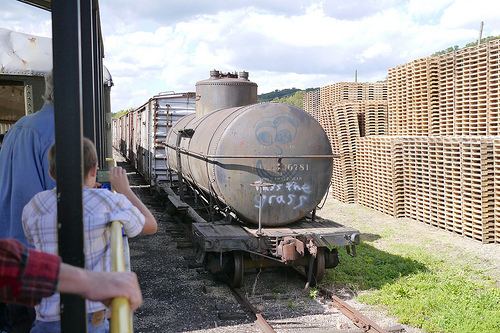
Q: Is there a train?
A: Yes, there is a train.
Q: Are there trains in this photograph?
A: Yes, there is a train.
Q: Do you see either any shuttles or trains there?
A: Yes, there is a train.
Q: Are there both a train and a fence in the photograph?
A: No, there is a train but no fences.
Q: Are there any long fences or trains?
A: Yes, there is a long train.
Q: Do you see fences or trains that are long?
A: Yes, the train is long.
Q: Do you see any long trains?
A: Yes, there is a long train.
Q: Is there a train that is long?
A: Yes, there is a train that is long.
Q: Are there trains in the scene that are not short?
A: Yes, there is a long train.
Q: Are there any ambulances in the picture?
A: No, there are no ambulances.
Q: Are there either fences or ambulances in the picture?
A: No, there are no ambulances or fences.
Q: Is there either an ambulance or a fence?
A: No, there are no ambulances or fences.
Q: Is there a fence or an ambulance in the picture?
A: No, there are no ambulances or fences.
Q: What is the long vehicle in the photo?
A: The vehicle is a train.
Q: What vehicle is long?
A: The vehicle is a train.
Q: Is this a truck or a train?
A: This is a train.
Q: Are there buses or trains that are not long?
A: No, there is a train but it is long.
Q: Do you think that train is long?
A: Yes, the train is long.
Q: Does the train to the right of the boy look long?
A: Yes, the train is long.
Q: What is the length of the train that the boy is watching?
A: The train is long.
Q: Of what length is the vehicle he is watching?
A: The train is long.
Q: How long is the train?
A: The train is long.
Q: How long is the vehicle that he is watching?
A: The train is long.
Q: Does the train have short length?
A: No, the train is long.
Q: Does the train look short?
A: No, the train is long.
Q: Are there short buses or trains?
A: No, there is a train but it is long.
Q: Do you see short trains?
A: No, there is a train but it is long.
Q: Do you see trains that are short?
A: No, there is a train but it is long.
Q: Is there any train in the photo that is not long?
A: No, there is a train but it is long.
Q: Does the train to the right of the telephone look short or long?
A: The train is long.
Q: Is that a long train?
A: Yes, that is a long train.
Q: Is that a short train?
A: No, that is a long train.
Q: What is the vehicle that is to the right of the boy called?
A: The vehicle is a train.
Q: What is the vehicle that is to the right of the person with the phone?
A: The vehicle is a train.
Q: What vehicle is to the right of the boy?
A: The vehicle is a train.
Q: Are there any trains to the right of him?
A: Yes, there is a train to the right of the boy.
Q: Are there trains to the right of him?
A: Yes, there is a train to the right of the boy.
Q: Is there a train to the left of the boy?
A: No, the train is to the right of the boy.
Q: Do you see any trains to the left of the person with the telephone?
A: No, the train is to the right of the boy.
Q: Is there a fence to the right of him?
A: No, there is a train to the right of the boy.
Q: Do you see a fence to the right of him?
A: No, there is a train to the right of the boy.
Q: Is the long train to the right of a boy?
A: Yes, the train is to the right of a boy.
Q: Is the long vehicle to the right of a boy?
A: Yes, the train is to the right of a boy.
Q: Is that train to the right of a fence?
A: No, the train is to the right of a boy.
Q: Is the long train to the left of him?
A: No, the train is to the right of the boy.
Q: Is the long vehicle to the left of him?
A: No, the train is to the right of the boy.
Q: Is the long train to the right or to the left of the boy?
A: The train is to the right of the boy.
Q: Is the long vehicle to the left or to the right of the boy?
A: The train is to the right of the boy.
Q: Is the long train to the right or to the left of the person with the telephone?
A: The train is to the right of the boy.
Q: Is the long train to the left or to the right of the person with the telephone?
A: The train is to the right of the boy.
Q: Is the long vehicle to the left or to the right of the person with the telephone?
A: The train is to the right of the boy.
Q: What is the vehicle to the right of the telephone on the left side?
A: The vehicle is a train.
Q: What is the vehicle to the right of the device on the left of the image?
A: The vehicle is a train.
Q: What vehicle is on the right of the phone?
A: The vehicle is a train.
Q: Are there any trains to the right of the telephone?
A: Yes, there is a train to the right of the telephone.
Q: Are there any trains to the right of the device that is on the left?
A: Yes, there is a train to the right of the telephone.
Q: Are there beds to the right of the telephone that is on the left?
A: No, there is a train to the right of the telephone.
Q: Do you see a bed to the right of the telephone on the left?
A: No, there is a train to the right of the telephone.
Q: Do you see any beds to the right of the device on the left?
A: No, there is a train to the right of the telephone.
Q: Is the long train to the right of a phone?
A: Yes, the train is to the right of a phone.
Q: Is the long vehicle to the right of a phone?
A: Yes, the train is to the right of a phone.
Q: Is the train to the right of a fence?
A: No, the train is to the right of a phone.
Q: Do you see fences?
A: No, there are no fences.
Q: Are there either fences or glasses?
A: No, there are no fences or glasses.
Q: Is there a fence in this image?
A: No, there are no fences.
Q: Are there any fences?
A: No, there are no fences.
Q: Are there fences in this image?
A: No, there are no fences.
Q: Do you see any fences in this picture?
A: No, there are no fences.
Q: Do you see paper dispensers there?
A: No, there are no paper dispensers.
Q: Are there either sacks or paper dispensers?
A: No, there are no paper dispensers or sacks.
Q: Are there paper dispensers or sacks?
A: No, there are no paper dispensers or sacks.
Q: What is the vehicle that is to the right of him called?
A: The vehicle is a train car.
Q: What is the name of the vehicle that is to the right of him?
A: The vehicle is a train car.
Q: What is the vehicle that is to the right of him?
A: The vehicle is a train car.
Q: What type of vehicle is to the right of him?
A: The vehicle is a train car.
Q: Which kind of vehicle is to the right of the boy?
A: The vehicle is a train car.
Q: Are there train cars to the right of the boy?
A: Yes, there is a train car to the right of the boy.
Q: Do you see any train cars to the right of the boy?
A: Yes, there is a train car to the right of the boy.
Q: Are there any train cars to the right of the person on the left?
A: Yes, there is a train car to the right of the boy.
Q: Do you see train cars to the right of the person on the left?
A: Yes, there is a train car to the right of the boy.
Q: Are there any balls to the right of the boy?
A: No, there is a train car to the right of the boy.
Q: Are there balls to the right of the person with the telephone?
A: No, there is a train car to the right of the boy.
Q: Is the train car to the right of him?
A: Yes, the train car is to the right of a boy.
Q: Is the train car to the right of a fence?
A: No, the train car is to the right of a boy.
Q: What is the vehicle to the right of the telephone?
A: The vehicle is a train car.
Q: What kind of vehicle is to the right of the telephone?
A: The vehicle is a train car.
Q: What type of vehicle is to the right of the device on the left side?
A: The vehicle is a train car.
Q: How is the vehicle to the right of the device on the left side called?
A: The vehicle is a train car.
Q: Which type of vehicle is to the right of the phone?
A: The vehicle is a train car.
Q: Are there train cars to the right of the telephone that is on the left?
A: Yes, there is a train car to the right of the telephone.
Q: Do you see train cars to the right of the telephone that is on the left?
A: Yes, there is a train car to the right of the telephone.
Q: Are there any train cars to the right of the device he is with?
A: Yes, there is a train car to the right of the telephone.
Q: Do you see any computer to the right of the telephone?
A: No, there is a train car to the right of the telephone.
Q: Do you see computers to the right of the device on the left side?
A: No, there is a train car to the right of the telephone.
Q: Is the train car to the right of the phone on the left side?
A: Yes, the train car is to the right of the telephone.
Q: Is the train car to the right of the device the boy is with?
A: Yes, the train car is to the right of the telephone.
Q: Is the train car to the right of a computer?
A: No, the train car is to the right of the telephone.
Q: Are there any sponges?
A: No, there are no sponges.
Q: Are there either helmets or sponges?
A: No, there are no sponges or helmets.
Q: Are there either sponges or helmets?
A: No, there are no sponges or helmets.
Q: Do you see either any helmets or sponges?
A: No, there are no sponges or helmets.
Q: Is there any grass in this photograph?
A: Yes, there is grass.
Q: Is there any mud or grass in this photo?
A: Yes, there is grass.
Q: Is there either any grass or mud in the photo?
A: Yes, there is grass.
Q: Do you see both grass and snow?
A: No, there is grass but no snow.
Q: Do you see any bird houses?
A: No, there are no bird houses.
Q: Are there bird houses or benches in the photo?
A: No, there are no bird houses or benches.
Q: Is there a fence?
A: No, there are no fences.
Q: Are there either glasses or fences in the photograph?
A: No, there are no fences or glasses.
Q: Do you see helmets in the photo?
A: No, there are no helmets.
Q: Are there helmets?
A: No, there are no helmets.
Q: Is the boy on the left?
A: Yes, the boy is on the left of the image.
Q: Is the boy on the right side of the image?
A: No, the boy is on the left of the image.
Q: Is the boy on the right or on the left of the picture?
A: The boy is on the left of the image.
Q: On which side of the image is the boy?
A: The boy is on the left of the image.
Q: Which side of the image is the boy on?
A: The boy is on the left of the image.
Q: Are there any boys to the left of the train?
A: Yes, there is a boy to the left of the train.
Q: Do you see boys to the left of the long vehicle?
A: Yes, there is a boy to the left of the train.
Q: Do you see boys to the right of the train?
A: No, the boy is to the left of the train.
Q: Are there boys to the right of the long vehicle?
A: No, the boy is to the left of the train.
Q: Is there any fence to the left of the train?
A: No, there is a boy to the left of the train.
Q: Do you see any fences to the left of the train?
A: No, there is a boy to the left of the train.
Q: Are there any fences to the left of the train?
A: No, there is a boy to the left of the train.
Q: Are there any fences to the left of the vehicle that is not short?
A: No, there is a boy to the left of the train.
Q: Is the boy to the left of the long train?
A: Yes, the boy is to the left of the train.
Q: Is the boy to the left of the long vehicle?
A: Yes, the boy is to the left of the train.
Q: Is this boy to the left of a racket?
A: No, the boy is to the left of the train.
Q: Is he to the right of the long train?
A: No, the boy is to the left of the train.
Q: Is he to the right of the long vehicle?
A: No, the boy is to the left of the train.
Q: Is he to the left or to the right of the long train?
A: The boy is to the left of the train.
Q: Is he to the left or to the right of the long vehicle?
A: The boy is to the left of the train.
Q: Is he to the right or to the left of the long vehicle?
A: The boy is to the left of the train.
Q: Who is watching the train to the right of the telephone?
A: The boy is watching the train.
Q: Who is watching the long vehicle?
A: The boy is watching the train.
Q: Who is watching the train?
A: The boy is watching the train.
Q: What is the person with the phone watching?
A: The boy is watching the train.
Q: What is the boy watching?
A: The boy is watching the train.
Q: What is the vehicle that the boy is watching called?
A: The vehicle is a train.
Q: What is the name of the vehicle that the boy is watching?
A: The vehicle is a train.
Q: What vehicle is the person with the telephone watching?
A: The boy is watching the train.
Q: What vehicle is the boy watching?
A: The boy is watching the train.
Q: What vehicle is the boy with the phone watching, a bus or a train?
A: The boy is watching a train.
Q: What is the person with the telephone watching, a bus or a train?
A: The boy is watching a train.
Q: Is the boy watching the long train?
A: Yes, the boy is watching the train.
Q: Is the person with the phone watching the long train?
A: Yes, the boy is watching the train.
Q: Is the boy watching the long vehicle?
A: Yes, the boy is watching the train.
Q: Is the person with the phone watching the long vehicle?
A: Yes, the boy is watching the train.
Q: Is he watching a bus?
A: No, the boy is watching the train.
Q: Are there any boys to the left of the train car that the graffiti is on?
A: Yes, there is a boy to the left of the train car.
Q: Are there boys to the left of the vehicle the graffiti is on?
A: Yes, there is a boy to the left of the train car.